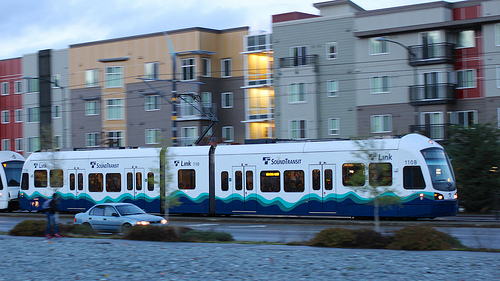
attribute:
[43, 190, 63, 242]
person — walking, alone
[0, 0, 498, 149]
building — red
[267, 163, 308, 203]
window — passenger 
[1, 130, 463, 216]
train — white, green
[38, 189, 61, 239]
person — standing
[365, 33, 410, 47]
street lamp — high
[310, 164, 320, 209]
door — closed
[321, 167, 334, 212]
door — closed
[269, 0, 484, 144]
building — gray 